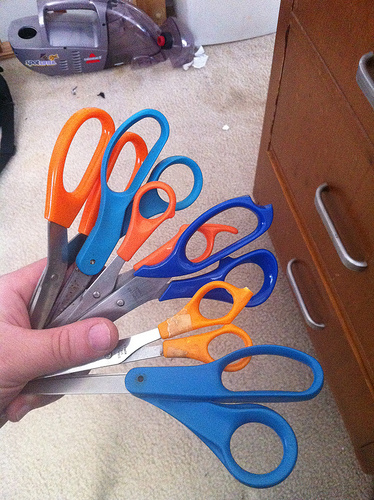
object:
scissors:
[42, 278, 254, 373]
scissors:
[44, 107, 203, 331]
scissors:
[79, 196, 279, 324]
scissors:
[27, 107, 149, 329]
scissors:
[19, 345, 325, 490]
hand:
[0, 258, 123, 435]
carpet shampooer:
[7, 0, 196, 77]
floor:
[0, 33, 373, 499]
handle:
[310, 181, 366, 275]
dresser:
[251, 0, 373, 472]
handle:
[283, 255, 326, 333]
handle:
[42, 107, 116, 231]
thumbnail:
[82, 318, 112, 354]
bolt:
[115, 297, 125, 307]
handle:
[124, 343, 325, 407]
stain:
[198, 68, 268, 120]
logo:
[80, 54, 102, 67]